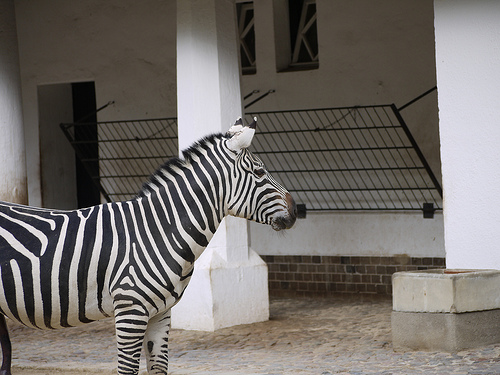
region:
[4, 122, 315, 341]
zebra is standing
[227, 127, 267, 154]
zebra has white ears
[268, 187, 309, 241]
zebra has brown nose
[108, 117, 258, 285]
zebra has vertical stripes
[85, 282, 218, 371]
zebra has striped legs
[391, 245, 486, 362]
concrete blocks near column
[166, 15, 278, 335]
column is white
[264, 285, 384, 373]
ground is white and bare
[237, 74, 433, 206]
wire cage near door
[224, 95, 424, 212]
metal cage near wall is black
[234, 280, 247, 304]
the post is white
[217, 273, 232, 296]
the post is white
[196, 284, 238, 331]
the post is white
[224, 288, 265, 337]
the post is white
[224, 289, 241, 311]
the post is white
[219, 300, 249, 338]
the post is white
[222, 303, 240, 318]
the post is white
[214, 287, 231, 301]
the post is white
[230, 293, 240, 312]
the post is white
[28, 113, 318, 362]
standing zebra facing right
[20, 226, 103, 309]
stripes on zebra body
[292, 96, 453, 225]
metal grate on wall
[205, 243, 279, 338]
base of white column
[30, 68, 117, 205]
open doorway on building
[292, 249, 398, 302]
bricks on bottom of wall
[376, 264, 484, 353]
two gray cement squares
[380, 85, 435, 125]
metal pole holding grate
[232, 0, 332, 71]
two open windows in wall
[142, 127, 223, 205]
man on zebra neck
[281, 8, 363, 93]
a window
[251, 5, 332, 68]
a window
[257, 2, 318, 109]
a window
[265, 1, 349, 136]
a window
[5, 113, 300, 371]
this is a zebra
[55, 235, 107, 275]
the fur is black and white in color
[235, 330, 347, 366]
this is the ground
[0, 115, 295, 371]
the zebra is standing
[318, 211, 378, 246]
this is the wall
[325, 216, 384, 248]
the wall is white in color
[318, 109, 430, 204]
these are some grills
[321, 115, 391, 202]
the grills are metallic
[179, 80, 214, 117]
this is a pillar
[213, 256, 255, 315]
the pillar is white in color